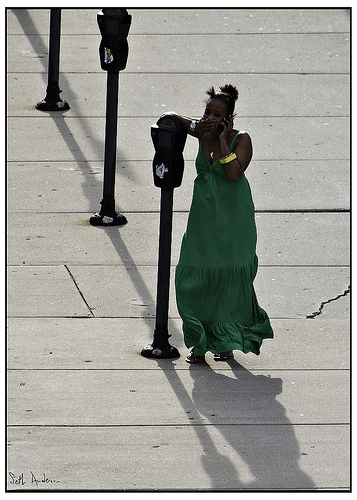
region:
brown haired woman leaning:
[161, 82, 274, 365]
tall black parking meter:
[139, 111, 187, 359]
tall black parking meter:
[90, 10, 132, 227]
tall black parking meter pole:
[41, 8, 68, 112]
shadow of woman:
[186, 356, 311, 487]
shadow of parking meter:
[154, 354, 240, 489]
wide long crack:
[301, 279, 347, 325]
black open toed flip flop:
[185, 348, 206, 363]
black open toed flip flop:
[214, 348, 234, 362]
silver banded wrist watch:
[184, 119, 196, 130]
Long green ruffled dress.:
[182, 157, 272, 336]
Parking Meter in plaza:
[91, 3, 135, 233]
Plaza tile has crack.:
[299, 268, 350, 328]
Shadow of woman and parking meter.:
[149, 347, 310, 482]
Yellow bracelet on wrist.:
[212, 148, 242, 175]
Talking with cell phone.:
[206, 97, 243, 138]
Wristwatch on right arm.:
[181, 114, 204, 136]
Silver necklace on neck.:
[198, 142, 220, 173]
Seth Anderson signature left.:
[6, 465, 69, 489]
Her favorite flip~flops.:
[184, 344, 243, 366]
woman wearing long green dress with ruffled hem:
[158, 73, 301, 368]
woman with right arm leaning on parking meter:
[146, 69, 282, 216]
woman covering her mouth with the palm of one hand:
[190, 75, 247, 144]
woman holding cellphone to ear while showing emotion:
[182, 79, 234, 143]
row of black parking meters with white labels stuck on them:
[31, 20, 196, 360]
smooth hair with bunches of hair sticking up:
[192, 74, 245, 102]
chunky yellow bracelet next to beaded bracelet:
[213, 130, 264, 177]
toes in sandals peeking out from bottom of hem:
[182, 341, 251, 376]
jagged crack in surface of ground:
[290, 267, 342, 334]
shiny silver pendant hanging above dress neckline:
[201, 145, 217, 167]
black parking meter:
[87, 9, 140, 234]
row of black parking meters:
[42, 7, 192, 358]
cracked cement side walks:
[265, 203, 349, 383]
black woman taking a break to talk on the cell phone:
[146, 87, 281, 380]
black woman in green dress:
[147, 89, 295, 365]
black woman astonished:
[155, 84, 284, 372]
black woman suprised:
[146, 76, 292, 383]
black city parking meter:
[87, 8, 151, 239]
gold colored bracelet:
[216, 124, 254, 191]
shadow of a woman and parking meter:
[179, 355, 316, 492]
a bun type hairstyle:
[196, 82, 253, 106]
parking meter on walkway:
[122, 106, 217, 370]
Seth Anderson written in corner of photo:
[5, 469, 72, 489]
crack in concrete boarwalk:
[291, 266, 353, 332]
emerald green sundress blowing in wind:
[171, 128, 273, 365]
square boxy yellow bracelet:
[217, 147, 239, 171]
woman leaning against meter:
[129, 77, 275, 365]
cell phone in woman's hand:
[207, 101, 249, 146]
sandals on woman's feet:
[173, 337, 240, 374]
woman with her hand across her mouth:
[154, 87, 256, 151]